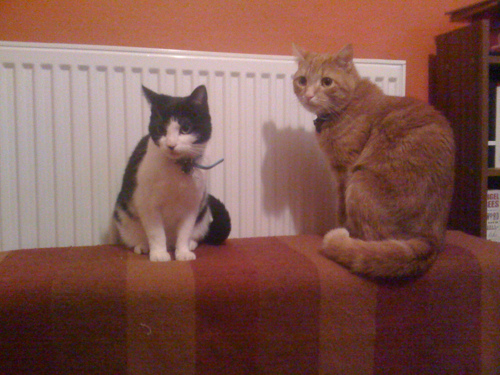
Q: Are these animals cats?
A: Yes, all the animals are cats.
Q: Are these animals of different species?
A: No, all the animals are cats.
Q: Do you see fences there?
A: No, there are no fences.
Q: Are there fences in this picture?
A: No, there are no fences.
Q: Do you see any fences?
A: No, there are no fences.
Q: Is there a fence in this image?
A: No, there are no fences.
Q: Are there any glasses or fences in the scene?
A: No, there are no fences or glasses.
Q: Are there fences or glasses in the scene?
A: No, there are no fences or glasses.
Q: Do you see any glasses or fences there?
A: No, there are no fences or glasses.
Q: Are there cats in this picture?
A: Yes, there is a cat.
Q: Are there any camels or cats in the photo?
A: Yes, there is a cat.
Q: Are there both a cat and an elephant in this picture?
A: No, there is a cat but no elephants.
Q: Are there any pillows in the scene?
A: No, there are no pillows.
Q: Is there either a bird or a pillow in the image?
A: No, there are no pillows or birds.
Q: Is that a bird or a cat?
A: That is a cat.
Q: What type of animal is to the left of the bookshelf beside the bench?
A: The animal is a cat.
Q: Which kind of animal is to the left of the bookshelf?
A: The animal is a cat.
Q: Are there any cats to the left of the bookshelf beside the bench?
A: Yes, there is a cat to the left of the bookshelf.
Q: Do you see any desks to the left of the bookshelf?
A: No, there is a cat to the left of the bookshelf.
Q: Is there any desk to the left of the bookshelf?
A: No, there is a cat to the left of the bookshelf.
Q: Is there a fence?
A: No, there are no fences.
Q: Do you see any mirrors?
A: No, there are no mirrors.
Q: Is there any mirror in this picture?
A: No, there are no mirrors.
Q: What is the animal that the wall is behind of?
A: The animal is a cat.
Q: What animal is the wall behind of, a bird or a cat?
A: The wall is behind a cat.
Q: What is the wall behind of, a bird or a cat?
A: The wall is behind a cat.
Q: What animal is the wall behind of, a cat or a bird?
A: The wall is behind a cat.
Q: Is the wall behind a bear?
A: No, the wall is behind a cat.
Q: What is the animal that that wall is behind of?
A: The animal is a cat.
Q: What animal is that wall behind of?
A: The wall is behind the cat.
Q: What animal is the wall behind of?
A: The wall is behind the cat.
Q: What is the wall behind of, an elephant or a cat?
A: The wall is behind a cat.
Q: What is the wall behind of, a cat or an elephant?
A: The wall is behind a cat.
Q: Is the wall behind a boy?
A: No, the wall is behind the cat.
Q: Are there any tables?
A: No, there are no tables.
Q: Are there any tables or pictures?
A: No, there are no tables or pictures.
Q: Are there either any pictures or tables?
A: No, there are no tables or pictures.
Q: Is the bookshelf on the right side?
A: Yes, the bookshelf is on the right of the image.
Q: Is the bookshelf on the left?
A: No, the bookshelf is on the right of the image.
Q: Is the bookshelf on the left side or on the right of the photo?
A: The bookshelf is on the right of the image.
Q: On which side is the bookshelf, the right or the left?
A: The bookshelf is on the right of the image.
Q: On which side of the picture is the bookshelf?
A: The bookshelf is on the right of the image.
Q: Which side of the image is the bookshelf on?
A: The bookshelf is on the right of the image.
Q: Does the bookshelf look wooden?
A: Yes, the bookshelf is wooden.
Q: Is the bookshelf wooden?
A: Yes, the bookshelf is wooden.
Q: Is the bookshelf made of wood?
A: Yes, the bookshelf is made of wood.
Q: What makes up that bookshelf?
A: The bookshelf is made of wood.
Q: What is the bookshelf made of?
A: The bookshelf is made of wood.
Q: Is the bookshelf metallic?
A: No, the bookshelf is wooden.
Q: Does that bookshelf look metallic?
A: No, the bookshelf is wooden.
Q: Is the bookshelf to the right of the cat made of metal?
A: No, the bookshelf is made of wood.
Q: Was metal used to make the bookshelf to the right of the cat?
A: No, the bookshelf is made of wood.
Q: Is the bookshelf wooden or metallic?
A: The bookshelf is wooden.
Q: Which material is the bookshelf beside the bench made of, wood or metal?
A: The bookshelf is made of wood.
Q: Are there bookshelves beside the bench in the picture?
A: Yes, there is a bookshelf beside the bench.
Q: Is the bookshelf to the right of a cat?
A: Yes, the bookshelf is to the right of a cat.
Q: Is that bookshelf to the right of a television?
A: No, the bookshelf is to the right of a cat.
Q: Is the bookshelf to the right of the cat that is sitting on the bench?
A: Yes, the bookshelf is to the right of the cat.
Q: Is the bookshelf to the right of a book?
A: No, the bookshelf is to the right of the cat.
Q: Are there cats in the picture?
A: Yes, there is a cat.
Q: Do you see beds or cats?
A: Yes, there is a cat.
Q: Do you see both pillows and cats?
A: No, there is a cat but no pillows.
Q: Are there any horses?
A: No, there are no horses.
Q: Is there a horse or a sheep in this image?
A: No, there are no horses or sheep.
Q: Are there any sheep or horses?
A: No, there are no horses or sheep.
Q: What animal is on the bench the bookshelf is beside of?
A: The cat is on the bench.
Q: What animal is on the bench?
A: The cat is on the bench.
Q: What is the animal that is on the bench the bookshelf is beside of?
A: The animal is a cat.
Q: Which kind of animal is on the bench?
A: The animal is a cat.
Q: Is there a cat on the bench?
A: Yes, there is a cat on the bench.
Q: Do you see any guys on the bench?
A: No, there is a cat on the bench.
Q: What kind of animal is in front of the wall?
A: The animal is a cat.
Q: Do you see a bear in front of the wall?
A: No, there is a cat in front of the wall.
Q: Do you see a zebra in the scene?
A: No, there are no zebras.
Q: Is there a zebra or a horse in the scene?
A: No, there are no zebras or horses.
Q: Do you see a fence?
A: No, there are no fences.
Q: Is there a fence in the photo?
A: No, there are no fences.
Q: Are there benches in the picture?
A: Yes, there is a bench.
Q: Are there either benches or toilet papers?
A: Yes, there is a bench.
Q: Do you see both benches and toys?
A: No, there is a bench but no toys.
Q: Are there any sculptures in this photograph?
A: No, there are no sculptures.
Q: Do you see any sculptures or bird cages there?
A: No, there are no sculptures or bird cages.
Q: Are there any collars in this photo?
A: Yes, there is a collar.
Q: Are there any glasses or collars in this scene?
A: Yes, there is a collar.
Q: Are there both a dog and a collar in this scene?
A: No, there is a collar but no dogs.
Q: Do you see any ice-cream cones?
A: No, there are no ice-cream cones.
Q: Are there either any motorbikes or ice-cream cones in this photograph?
A: No, there are no ice-cream cones or motorbikes.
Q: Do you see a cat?
A: Yes, there is a cat.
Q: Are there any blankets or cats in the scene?
A: Yes, there is a cat.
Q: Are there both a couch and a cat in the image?
A: No, there is a cat but no couches.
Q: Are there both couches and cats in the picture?
A: No, there is a cat but no couches.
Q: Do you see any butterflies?
A: No, there are no butterflies.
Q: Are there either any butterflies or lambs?
A: No, there are no butterflies or lambs.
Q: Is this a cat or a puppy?
A: This is a cat.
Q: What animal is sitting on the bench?
A: The cat is sitting on the bench.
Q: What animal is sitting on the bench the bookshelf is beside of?
A: The animal is a cat.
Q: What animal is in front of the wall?
A: The cat is in front of the wall.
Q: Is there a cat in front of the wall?
A: Yes, there is a cat in front of the wall.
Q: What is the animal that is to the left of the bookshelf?
A: The animal is a cat.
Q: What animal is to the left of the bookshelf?
A: The animal is a cat.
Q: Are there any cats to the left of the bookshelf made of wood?
A: Yes, there is a cat to the left of the bookshelf.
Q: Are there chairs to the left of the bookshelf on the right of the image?
A: No, there is a cat to the left of the bookshelf.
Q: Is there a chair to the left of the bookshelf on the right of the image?
A: No, there is a cat to the left of the bookshelf.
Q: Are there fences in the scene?
A: No, there are no fences.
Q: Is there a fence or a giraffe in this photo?
A: No, there are no fences or giraffes.